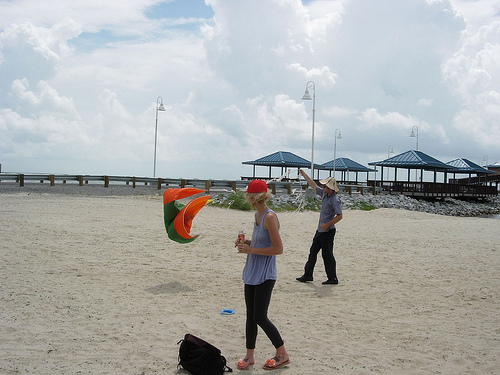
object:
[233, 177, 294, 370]
person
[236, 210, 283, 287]
top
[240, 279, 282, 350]
leggings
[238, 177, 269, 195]
cap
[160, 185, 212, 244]
kite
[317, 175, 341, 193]
hat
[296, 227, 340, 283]
pants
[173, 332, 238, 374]
bag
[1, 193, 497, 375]
sand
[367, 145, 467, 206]
pavilion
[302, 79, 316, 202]
light pole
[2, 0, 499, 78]
clouds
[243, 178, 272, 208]
head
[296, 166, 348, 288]
man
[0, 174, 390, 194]
guard rail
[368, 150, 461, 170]
roof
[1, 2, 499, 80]
sky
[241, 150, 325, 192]
pavilion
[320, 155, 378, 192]
pavilion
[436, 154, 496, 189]
pavilion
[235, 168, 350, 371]
two people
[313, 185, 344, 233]
vest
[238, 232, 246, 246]
drink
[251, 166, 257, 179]
support pole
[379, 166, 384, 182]
support pole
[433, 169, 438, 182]
support pole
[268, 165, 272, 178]
support pole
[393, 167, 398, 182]
support pole